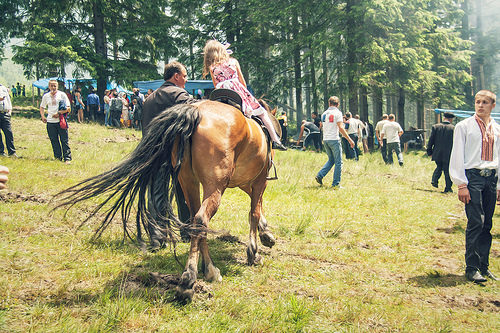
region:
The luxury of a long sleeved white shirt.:
[449, 117, 497, 187]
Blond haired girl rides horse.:
[202, 29, 292, 153]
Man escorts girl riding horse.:
[151, 32, 278, 167]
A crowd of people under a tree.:
[73, 32, 136, 128]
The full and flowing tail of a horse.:
[70, 99, 212, 246]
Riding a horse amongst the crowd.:
[29, 27, 497, 308]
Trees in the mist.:
[307, 0, 497, 92]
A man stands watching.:
[37, 77, 80, 167]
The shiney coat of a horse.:
[204, 114, 249, 184]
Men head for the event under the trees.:
[290, 18, 428, 207]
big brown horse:
[51, 100, 282, 300]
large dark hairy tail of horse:
[41, 90, 201, 258]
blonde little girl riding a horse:
[203, 40, 285, 150]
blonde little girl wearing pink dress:
[198, 38, 284, 151]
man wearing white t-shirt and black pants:
[36, 76, 74, 161]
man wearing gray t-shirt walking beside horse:
[138, 61, 196, 248]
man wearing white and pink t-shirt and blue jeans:
[447, 90, 497, 283]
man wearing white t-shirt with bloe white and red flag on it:
[315, 95, 351, 190]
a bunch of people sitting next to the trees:
[65, 85, 426, 165]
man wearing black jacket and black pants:
[427, 112, 456, 194]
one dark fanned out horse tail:
[66, 100, 200, 242]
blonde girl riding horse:
[191, 38, 270, 158]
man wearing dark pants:
[445, 89, 499, 281]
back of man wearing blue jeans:
[313, 94, 358, 186]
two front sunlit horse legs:
[239, 178, 279, 264]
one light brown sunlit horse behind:
[172, 103, 222, 174]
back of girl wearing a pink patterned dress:
[201, 38, 268, 119]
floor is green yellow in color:
[294, 234, 399, 289]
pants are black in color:
[468, 183, 498, 263]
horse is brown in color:
[183, 103, 269, 191]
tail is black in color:
[114, 108, 188, 204]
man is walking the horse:
[151, 58, 238, 188]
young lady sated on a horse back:
[202, 40, 267, 132]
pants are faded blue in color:
[320, 141, 347, 181]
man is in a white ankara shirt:
[45, 93, 74, 115]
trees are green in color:
[326, 15, 389, 75]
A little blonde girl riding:
[195, 39, 288, 130]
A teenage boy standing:
[462, 84, 494, 288]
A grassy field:
[26, 288, 229, 329]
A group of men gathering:
[308, 90, 418, 198]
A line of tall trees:
[250, 15, 485, 95]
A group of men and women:
[70, 83, 145, 130]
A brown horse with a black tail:
[81, 96, 303, 283]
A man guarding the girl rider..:
[148, 57, 195, 105]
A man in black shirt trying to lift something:
[288, 115, 325, 155]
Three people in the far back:
[7, 76, 29, 105]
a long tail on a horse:
[47, 107, 214, 258]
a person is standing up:
[438, 85, 499, 285]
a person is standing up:
[309, 90, 356, 185]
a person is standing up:
[146, 57, 201, 246]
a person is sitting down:
[199, 39, 289, 154]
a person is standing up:
[377, 103, 404, 162]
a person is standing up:
[351, 113, 364, 149]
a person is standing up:
[301, 115, 316, 143]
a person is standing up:
[42, 75, 74, 160]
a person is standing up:
[107, 91, 125, 125]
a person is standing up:
[85, 87, 102, 122]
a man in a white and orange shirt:
[446, 89, 498, 286]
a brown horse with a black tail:
[48, 98, 285, 308]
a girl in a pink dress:
[200, 38, 287, 152]